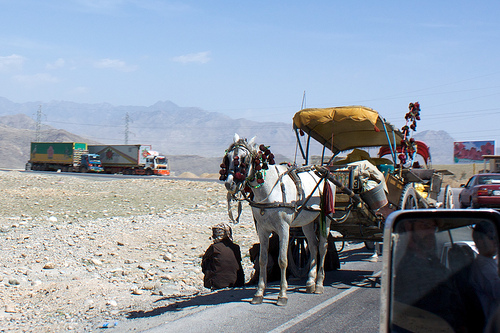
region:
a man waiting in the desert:
[195, 221, 238, 285]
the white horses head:
[218, 142, 255, 189]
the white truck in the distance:
[97, 141, 167, 171]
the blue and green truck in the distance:
[24, 141, 101, 172]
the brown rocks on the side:
[78, 240, 115, 290]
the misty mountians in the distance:
[161, 103, 185, 129]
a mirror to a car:
[381, 203, 496, 325]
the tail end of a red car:
[469, 177, 494, 204]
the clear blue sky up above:
[202, 63, 254, 95]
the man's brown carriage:
[283, 95, 398, 149]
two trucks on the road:
[28, 140, 170, 177]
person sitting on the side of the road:
[202, 223, 245, 289]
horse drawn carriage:
[219, 105, 449, 305]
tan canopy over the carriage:
[292, 106, 412, 168]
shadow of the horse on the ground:
[124, 286, 296, 318]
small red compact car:
[456, 173, 498, 207]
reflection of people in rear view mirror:
[378, 206, 498, 331]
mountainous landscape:
[1, 96, 454, 152]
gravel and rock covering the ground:
[2, 170, 244, 327]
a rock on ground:
[41, 258, 56, 271]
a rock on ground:
[84, 256, 113, 267]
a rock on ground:
[124, 277, 144, 299]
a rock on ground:
[137, 259, 149, 270]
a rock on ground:
[139, 276, 157, 291]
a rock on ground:
[155, 263, 181, 294]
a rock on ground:
[162, 235, 174, 249]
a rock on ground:
[164, 250, 181, 268]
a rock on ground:
[142, 195, 159, 225]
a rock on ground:
[178, 195, 198, 215]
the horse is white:
[204, 132, 344, 310]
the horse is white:
[196, 128, 351, 328]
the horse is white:
[198, 115, 358, 321]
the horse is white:
[202, 123, 341, 332]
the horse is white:
[215, 134, 333, 332]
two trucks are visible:
[12, 125, 172, 195]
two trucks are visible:
[29, 134, 194, 191]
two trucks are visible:
[10, 121, 185, 194]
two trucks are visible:
[3, 125, 191, 187]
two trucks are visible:
[17, 124, 179, 209]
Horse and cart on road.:
[216, 97, 465, 306]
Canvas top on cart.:
[293, 104, 411, 156]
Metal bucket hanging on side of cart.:
[363, 176, 394, 217]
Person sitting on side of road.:
[194, 217, 253, 295]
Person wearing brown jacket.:
[193, 237, 249, 292]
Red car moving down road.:
[456, 168, 499, 206]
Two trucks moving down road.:
[23, 132, 171, 182]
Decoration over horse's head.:
[213, 139, 278, 188]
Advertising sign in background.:
[448, 135, 499, 166]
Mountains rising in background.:
[126, 91, 293, 155]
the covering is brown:
[294, 106, 378, 126]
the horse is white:
[221, 138, 331, 287]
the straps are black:
[255, 162, 320, 210]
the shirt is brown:
[202, 243, 244, 285]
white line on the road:
[270, 272, 372, 332]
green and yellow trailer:
[30, 143, 88, 168]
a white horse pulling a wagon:
[219, 98, 455, 305]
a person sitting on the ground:
[202, 223, 248, 295]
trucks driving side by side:
[25, 141, 170, 176]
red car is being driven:
[456, 171, 498, 207]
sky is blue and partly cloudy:
[0, 0, 498, 139]